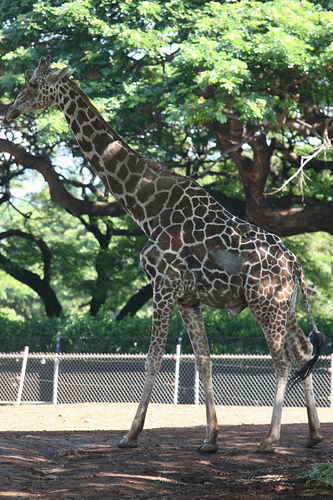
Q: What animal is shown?
A: Giraffe.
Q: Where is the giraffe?
A: IN a zoo.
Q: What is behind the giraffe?
A: Fence.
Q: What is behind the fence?
A: Trees.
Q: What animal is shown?
A: Giraffe.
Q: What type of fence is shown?
A: Chain link.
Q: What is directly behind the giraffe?
A: Tree.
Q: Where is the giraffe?
A: In the shade.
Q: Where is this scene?
A: Zoo.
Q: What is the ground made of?
A: Dirt.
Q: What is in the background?
A: Fence.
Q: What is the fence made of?
A: Metal.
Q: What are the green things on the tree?
A: Leaves.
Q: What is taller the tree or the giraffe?
A: Tree.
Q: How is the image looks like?
A: Good.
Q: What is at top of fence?
A: Barbed wire.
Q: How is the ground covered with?
A: Dirt.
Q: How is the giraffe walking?
A: Enclosure.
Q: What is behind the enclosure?
A: Trees.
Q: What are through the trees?
A: Sunshine.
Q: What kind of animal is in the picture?
A: A giraffe.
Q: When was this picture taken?
A: During the day.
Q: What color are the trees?
A: Green.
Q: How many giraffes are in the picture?
A: One.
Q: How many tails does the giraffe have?
A: One.